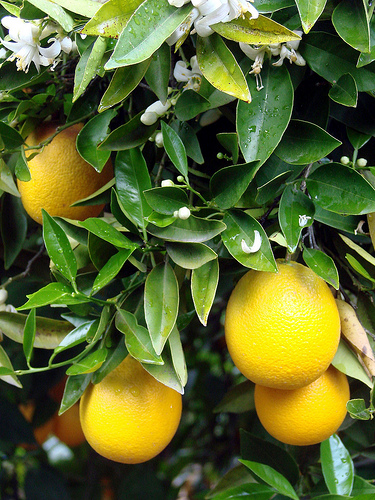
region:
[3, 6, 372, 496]
lemons in a tree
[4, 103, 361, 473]
four lemons hanging from a tree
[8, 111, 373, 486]
four lemons color yellow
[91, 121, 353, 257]
green leaves of a lemon tree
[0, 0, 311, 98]
white flowers of a lemon tree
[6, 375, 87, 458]
two are lemons behind the leaves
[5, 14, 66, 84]
a white flower on a lemon tree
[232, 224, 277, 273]
a white petal on a green leaf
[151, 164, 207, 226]
small flower buttons color white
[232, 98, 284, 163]
drops of water on a leaf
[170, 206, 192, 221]
A white flower bud.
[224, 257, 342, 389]
A yellow type rounded fruit.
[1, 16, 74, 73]
A blooming white flower.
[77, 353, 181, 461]
An yellow rounded fruit.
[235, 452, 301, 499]
A green leaf hanging from vegetation.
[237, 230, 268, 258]
A part of a white flower petal.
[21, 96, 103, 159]
A part of a green stem of the vegetation.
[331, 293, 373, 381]
A yellowing leaf from the vegetation.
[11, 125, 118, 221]
a yellow rounded fruit.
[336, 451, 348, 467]
A water droplet on a green leaf.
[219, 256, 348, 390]
orange on a tree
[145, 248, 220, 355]
green leaves on a tree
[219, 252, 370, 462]
a couple of oranges on a tree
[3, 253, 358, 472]
a group of oranges on a tree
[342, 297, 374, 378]
a spotted leave on the tree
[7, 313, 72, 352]
a light green leaf on a tree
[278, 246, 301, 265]
stem of a orange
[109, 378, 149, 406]
drops of water on the orange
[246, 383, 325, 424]
shodow of a orange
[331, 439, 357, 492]
drops of water on a leaf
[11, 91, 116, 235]
orange surrounded by green leaves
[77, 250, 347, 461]
oranges hanging from tree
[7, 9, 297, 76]
white blossoms over and under leaves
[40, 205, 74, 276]
pointy leaf with drops of water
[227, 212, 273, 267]
white petal resting on leaf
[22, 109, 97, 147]
green branch in front of orange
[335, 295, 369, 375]
curled tan leaf with black spots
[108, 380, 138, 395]
drops of water on an orange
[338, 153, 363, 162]
two white buds on either side of stem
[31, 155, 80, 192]
porous texture of orange peel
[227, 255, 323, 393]
orange colored fruit handing from tree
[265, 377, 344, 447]
orange colored fruit handing from tree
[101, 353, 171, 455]
orange colored fruit handing from tree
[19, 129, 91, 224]
orange colored fruit handing from tree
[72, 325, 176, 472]
orange colored fruit with green leaves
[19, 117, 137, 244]
orange colored fruit with green leaves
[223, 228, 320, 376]
orange colored fruit with green leaves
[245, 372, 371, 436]
orange colored fruit with green leaves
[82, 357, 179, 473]
orange fruit with green leaves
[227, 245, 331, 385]
orange fruit with green leaves